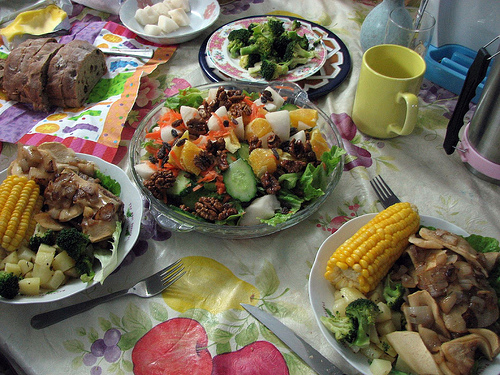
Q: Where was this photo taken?
A: At a restaurant.